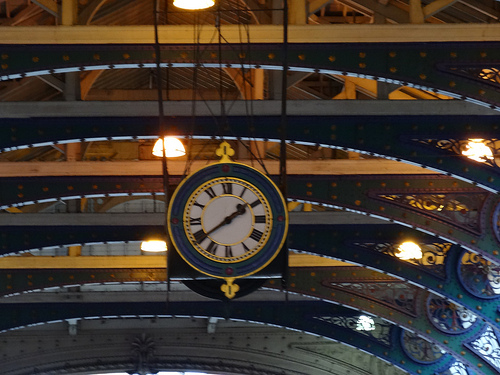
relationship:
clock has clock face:
[165, 162, 289, 279] [182, 177, 275, 264]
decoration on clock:
[216, 141, 234, 164] [165, 162, 289, 279]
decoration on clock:
[215, 277, 244, 300] [165, 162, 289, 279]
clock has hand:
[165, 162, 289, 279] [229, 202, 251, 224]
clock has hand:
[165, 162, 289, 279] [190, 222, 230, 248]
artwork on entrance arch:
[125, 332, 159, 374] [115, 322, 254, 372]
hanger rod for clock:
[152, 2, 170, 198] [164, 137, 292, 302]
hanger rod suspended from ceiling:
[152, 2, 171, 202] [0, 3, 484, 373]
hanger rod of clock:
[152, 2, 171, 202] [164, 136, 309, 282]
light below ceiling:
[147, 135, 179, 163] [14, 30, 436, 140]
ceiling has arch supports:
[298, 163, 478, 278] [17, 79, 451, 279]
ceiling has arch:
[3, 78, 371, 102] [0, 58, 500, 123]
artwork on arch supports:
[129, 331, 155, 359] [1, 314, 448, 375]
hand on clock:
[203, 199, 250, 241] [162, 155, 292, 283]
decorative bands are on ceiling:
[102, 67, 280, 100] [50, 32, 394, 258]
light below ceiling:
[152, 135, 186, 159] [0, 3, 484, 373]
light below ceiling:
[461, 135, 495, 162] [407, 93, 491, 181]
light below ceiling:
[394, 237, 424, 262] [3, 3, 499, 292]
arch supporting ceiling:
[7, 103, 493, 188] [3, 78, 371, 102]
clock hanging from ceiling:
[164, 137, 292, 302] [0, 3, 484, 373]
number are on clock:
[225, 246, 233, 257] [164, 137, 292, 302]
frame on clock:
[161, 160, 292, 282] [162, 161, 287, 278]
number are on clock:
[225, 246, 233, 257] [178, 168, 277, 286]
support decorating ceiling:
[0, 314, 412, 375] [0, 3, 484, 373]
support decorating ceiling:
[2, 295, 460, 373] [0, 3, 484, 373]